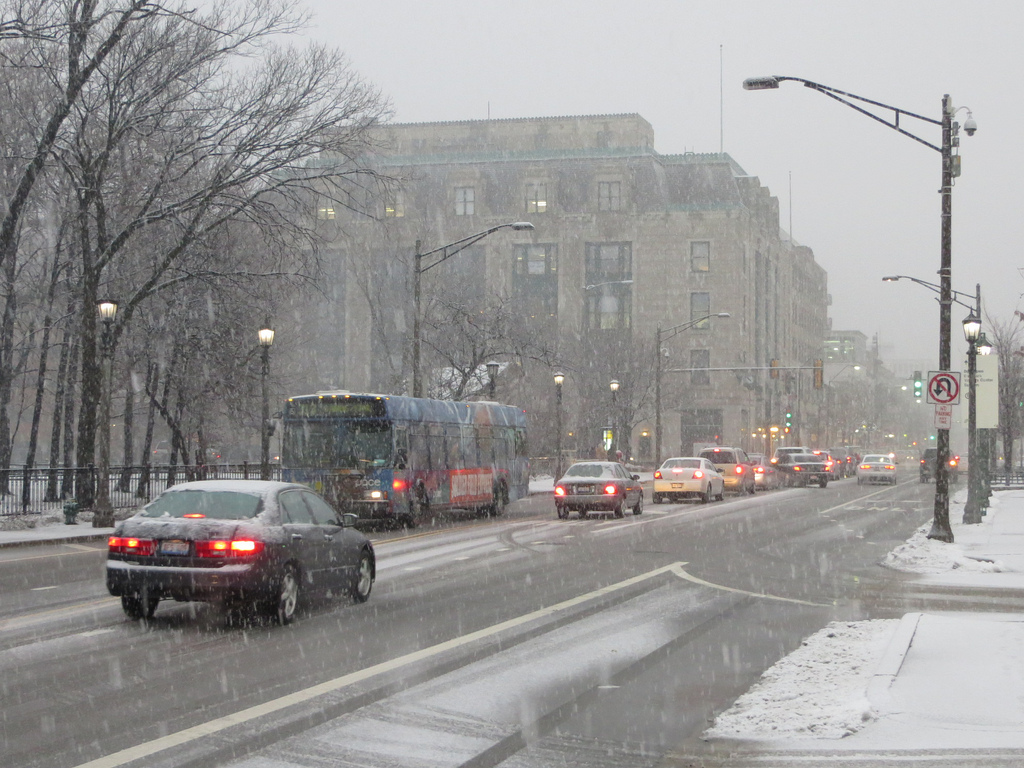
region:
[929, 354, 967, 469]
a sign is on a post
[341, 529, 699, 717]
road has white line marked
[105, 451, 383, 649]
A car has its red rear lights on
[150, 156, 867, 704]
Snow is falling to the ground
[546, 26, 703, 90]
Sky is very cloudy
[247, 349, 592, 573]
A city bus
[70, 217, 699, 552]
Street lamps along the street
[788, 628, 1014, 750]
Snow on the ground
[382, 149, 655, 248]
Windows on a building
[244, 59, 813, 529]
A large brown building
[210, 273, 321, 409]
A street lamp is turned on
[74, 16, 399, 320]
Trees with no leaves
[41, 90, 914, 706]
White snow is falling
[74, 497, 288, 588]
Rear lights of a car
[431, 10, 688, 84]
The sky is very overcast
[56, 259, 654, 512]
Street lamps lined up side by side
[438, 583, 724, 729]
Snow on the street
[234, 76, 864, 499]
A large building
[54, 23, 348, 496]
Tree with no leaves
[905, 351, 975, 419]
White, red and black sign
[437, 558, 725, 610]
White line on the street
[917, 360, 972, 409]
a no u-turn sign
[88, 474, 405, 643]
the back of a car covered in snow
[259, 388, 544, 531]
a city bus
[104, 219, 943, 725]
a snowy street full of parked cars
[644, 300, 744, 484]
a city lamp post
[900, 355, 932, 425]
a green traffic light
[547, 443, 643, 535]
a stopped vehicle covered with snow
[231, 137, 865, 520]
a brown building on a snowy day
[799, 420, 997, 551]
a turn lane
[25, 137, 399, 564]
a barren tree in the winter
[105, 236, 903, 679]
It is snowing everywhere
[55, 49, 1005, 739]
It is winter season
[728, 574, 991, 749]
snow on the street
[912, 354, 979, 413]
the no u-turn sign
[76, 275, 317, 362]
lamp posts are on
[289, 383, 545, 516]
the bus is blue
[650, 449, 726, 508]
the car is white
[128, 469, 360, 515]
the roof has snow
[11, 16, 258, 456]
trees have no leaves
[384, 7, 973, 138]
the sky is gray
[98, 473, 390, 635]
compact car with brake lights on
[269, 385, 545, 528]
a public bus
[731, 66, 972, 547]
a streetlight that is not turned on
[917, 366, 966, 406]
a "no U-turns" sign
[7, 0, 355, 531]
trees along the sidewalk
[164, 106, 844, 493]
an old office building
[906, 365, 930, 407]
a green traffic signal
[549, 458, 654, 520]
a small car waiting in traffic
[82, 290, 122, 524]
an old fashioned street light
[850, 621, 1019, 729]
snow on the sidewalk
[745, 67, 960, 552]
a lamp post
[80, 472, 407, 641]
a snow covered car driving down the street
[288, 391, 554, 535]
a bus driving down the road during a snow storm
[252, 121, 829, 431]
a large building in the distance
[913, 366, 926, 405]
a traffic light in on green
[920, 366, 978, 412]
a sign indicating u-turns are prohibited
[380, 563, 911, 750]
the road is covered with snow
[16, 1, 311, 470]
trees don't have leaves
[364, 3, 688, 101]
a grey and overcast sky